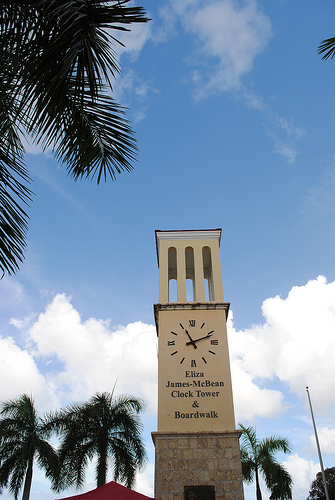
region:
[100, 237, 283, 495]
a clock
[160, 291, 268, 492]
a clock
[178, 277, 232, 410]
a clock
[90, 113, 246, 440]
a clock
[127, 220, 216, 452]
a clock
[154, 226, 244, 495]
the tower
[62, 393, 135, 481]
the palm tree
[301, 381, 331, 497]
the flag pole beside the tower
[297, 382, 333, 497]
the flag pole is metal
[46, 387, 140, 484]
the leaves of the palm tree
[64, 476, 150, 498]
the burgundy tent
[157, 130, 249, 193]
the clear blue sky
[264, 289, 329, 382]
the clouds in the sky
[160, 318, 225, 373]
the clock on the tower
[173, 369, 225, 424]
the writing on the tower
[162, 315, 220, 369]
clock on face of tower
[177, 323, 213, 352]
two hands on clock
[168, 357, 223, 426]
black words underneath clock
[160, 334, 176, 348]
roman numeral on clock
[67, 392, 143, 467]
leaves on palm tree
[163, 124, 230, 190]
blue of daytime sky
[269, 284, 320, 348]
white cloud in sky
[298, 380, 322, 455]
tall metal flag pole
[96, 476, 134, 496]
top of red roof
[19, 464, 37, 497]
trunk of palm tree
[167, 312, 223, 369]
clock on tall tower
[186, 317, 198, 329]
roman numeral on clock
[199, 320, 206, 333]
roman numeral on clock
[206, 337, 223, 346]
roman numeral on clock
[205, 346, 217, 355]
roman numeral on clock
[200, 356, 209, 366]
roman numeral on clock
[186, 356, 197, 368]
roman numeral on clock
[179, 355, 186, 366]
roman numeral on clock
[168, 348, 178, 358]
roman numeral on clock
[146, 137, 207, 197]
light blue sky between clouds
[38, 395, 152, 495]
a tall palm tree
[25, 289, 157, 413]
a white cloud in the sky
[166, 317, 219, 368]
a clock with roman numerals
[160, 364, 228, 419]
black words on building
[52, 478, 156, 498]
a red roof or tent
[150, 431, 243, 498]
beige colored bricks on buildings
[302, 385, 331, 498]
a skinny tall pole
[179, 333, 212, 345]
minute hand of clock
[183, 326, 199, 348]
hour hand of clock